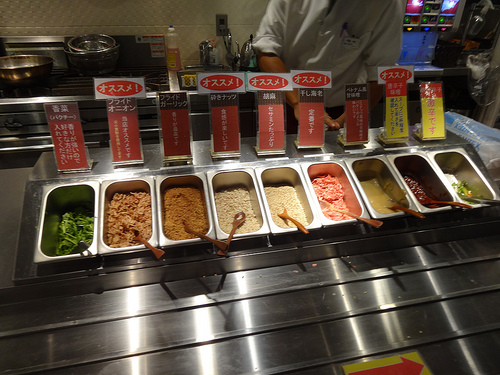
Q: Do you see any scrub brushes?
A: No, there are no scrub brushes.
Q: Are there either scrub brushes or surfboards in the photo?
A: No, there are no scrub brushes or surfboards.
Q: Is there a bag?
A: No, there are no bags.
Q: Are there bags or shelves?
A: No, there are no bags or shelves.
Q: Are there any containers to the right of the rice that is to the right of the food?
A: Yes, there is a container to the right of the rice.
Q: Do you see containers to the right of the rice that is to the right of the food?
A: Yes, there is a container to the right of the rice.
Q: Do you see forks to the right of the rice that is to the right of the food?
A: No, there is a container to the right of the rice.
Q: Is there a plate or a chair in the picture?
A: No, there are no chairs or plates.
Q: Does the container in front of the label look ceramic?
A: No, the container is metallic.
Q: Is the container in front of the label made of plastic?
A: No, the container is made of metal.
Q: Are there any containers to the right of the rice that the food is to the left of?
A: Yes, there is a container to the right of the rice.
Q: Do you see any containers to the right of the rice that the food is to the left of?
A: Yes, there is a container to the right of the rice.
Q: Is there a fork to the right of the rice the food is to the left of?
A: No, there is a container to the right of the rice.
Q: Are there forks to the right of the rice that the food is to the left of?
A: No, there is a container to the right of the rice.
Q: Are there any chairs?
A: No, there are no chairs.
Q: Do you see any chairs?
A: No, there are no chairs.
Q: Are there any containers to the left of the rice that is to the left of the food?
A: Yes, there is a container to the left of the rice.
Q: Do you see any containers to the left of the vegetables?
A: No, the container is to the right of the vegetables.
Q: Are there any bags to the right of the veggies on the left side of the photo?
A: No, there is a container to the right of the vegetables.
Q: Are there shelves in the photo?
A: No, there are no shelves.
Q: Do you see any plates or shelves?
A: No, there are no shelves or plates.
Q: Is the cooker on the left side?
A: Yes, the cooker is on the left of the image.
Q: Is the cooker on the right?
A: No, the cooker is on the left of the image.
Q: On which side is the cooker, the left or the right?
A: The cooker is on the left of the image.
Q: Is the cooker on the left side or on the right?
A: The cooker is on the left of the image.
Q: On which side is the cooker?
A: The cooker is on the left of the image.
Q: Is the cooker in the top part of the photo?
A: Yes, the cooker is in the top of the image.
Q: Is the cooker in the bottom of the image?
A: No, the cooker is in the top of the image.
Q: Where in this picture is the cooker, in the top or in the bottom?
A: The cooker is in the top of the image.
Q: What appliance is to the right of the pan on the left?
A: The appliance is a cooker.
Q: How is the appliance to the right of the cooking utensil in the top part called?
A: The appliance is a cooker.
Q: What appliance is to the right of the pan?
A: The appliance is a cooker.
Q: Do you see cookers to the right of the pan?
A: Yes, there is a cooker to the right of the pan.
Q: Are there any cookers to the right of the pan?
A: Yes, there is a cooker to the right of the pan.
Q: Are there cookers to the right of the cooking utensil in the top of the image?
A: Yes, there is a cooker to the right of the pan.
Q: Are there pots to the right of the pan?
A: No, there is a cooker to the right of the pan.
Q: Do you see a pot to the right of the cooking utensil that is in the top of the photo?
A: No, there is a cooker to the right of the pan.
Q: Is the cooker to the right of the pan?
A: Yes, the cooker is to the right of the pan.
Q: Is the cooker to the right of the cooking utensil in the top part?
A: Yes, the cooker is to the right of the pan.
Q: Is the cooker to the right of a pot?
A: No, the cooker is to the right of the pan.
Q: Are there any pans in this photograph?
A: Yes, there is a pan.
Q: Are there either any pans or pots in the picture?
A: Yes, there is a pan.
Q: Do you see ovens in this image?
A: No, there are no ovens.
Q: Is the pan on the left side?
A: Yes, the pan is on the left of the image.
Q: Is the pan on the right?
A: No, the pan is on the left of the image.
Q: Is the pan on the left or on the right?
A: The pan is on the left of the image.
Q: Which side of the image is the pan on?
A: The pan is on the left of the image.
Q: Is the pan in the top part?
A: Yes, the pan is in the top of the image.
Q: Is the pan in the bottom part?
A: No, the pan is in the top of the image.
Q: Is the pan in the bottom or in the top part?
A: The pan is in the top of the image.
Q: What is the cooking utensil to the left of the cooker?
A: The cooking utensil is a pan.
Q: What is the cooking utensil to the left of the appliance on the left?
A: The cooking utensil is a pan.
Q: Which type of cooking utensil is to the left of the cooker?
A: The cooking utensil is a pan.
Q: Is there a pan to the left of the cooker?
A: Yes, there is a pan to the left of the cooker.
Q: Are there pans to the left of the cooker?
A: Yes, there is a pan to the left of the cooker.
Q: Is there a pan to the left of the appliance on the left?
A: Yes, there is a pan to the left of the cooker.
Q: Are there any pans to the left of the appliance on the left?
A: Yes, there is a pan to the left of the cooker.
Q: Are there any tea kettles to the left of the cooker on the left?
A: No, there is a pan to the left of the cooker.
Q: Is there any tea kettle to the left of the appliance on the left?
A: No, there is a pan to the left of the cooker.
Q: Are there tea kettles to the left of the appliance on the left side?
A: No, there is a pan to the left of the cooker.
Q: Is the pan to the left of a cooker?
A: Yes, the pan is to the left of a cooker.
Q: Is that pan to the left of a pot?
A: No, the pan is to the left of a cooker.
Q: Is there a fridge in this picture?
A: No, there are no refrigerators.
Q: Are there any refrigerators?
A: No, there are no refrigerators.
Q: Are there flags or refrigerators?
A: No, there are no refrigerators or flags.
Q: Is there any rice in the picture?
A: Yes, there is rice.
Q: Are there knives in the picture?
A: No, there are no knives.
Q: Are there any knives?
A: No, there are no knives.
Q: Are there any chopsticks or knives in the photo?
A: No, there are no knives or chopsticks.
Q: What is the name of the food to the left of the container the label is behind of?
A: The food is rice.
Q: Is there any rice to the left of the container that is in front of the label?
A: Yes, there is rice to the left of the container.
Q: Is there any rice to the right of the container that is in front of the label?
A: No, the rice is to the left of the container.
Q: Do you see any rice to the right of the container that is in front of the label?
A: No, the rice is to the left of the container.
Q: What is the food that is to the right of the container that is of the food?
A: The food is rice.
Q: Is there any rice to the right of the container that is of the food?
A: Yes, there is rice to the right of the container.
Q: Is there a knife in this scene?
A: No, there are no knives.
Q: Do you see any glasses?
A: No, there are no glasses.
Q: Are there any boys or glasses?
A: No, there are no glasses or boys.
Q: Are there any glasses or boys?
A: No, there are no glasses or boys.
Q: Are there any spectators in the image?
A: No, there are no spectators.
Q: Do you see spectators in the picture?
A: No, there are no spectators.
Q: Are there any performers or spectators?
A: No, there are no spectators or performers.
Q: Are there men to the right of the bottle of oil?
A: Yes, there is a man to the right of the bottle.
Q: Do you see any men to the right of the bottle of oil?
A: Yes, there is a man to the right of the bottle.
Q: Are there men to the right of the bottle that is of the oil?
A: Yes, there is a man to the right of the bottle.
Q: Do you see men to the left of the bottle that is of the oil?
A: No, the man is to the right of the bottle.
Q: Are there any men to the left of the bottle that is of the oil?
A: No, the man is to the right of the bottle.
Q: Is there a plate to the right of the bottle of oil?
A: No, there is a man to the right of the bottle.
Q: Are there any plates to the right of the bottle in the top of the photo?
A: No, there is a man to the right of the bottle.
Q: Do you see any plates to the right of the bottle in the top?
A: No, there is a man to the right of the bottle.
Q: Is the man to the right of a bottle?
A: Yes, the man is to the right of a bottle.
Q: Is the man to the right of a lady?
A: No, the man is to the right of a bottle.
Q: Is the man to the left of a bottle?
A: No, the man is to the right of a bottle.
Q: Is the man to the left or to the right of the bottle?
A: The man is to the right of the bottle.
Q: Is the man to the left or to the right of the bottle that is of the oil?
A: The man is to the right of the bottle.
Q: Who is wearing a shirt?
A: The man is wearing a shirt.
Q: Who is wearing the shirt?
A: The man is wearing a shirt.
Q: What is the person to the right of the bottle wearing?
A: The man is wearing a shirt.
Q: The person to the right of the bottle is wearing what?
A: The man is wearing a shirt.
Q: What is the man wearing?
A: The man is wearing a shirt.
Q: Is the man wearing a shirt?
A: Yes, the man is wearing a shirt.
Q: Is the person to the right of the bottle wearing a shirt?
A: Yes, the man is wearing a shirt.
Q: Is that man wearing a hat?
A: No, the man is wearing a shirt.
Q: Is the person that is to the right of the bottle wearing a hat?
A: No, the man is wearing a shirt.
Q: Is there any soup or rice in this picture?
A: Yes, there is rice.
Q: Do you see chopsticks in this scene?
A: No, there are no chopsticks.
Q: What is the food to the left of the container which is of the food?
A: The food is rice.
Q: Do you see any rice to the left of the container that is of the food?
A: Yes, there is rice to the left of the container.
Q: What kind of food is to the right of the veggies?
A: The food is rice.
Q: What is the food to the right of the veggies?
A: The food is rice.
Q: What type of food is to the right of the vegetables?
A: The food is rice.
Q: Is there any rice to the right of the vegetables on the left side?
A: Yes, there is rice to the right of the vegetables.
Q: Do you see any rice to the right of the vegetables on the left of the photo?
A: Yes, there is rice to the right of the vegetables.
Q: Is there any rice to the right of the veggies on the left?
A: Yes, there is rice to the right of the vegetables.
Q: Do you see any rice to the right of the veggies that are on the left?
A: Yes, there is rice to the right of the vegetables.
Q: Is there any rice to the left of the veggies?
A: No, the rice is to the right of the veggies.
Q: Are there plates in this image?
A: No, there are no plates.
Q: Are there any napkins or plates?
A: No, there are no plates or napkins.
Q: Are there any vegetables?
A: Yes, there are vegetables.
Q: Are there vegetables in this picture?
A: Yes, there are vegetables.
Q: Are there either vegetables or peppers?
A: Yes, there are vegetables.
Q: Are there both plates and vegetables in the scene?
A: No, there are vegetables but no plates.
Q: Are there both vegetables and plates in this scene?
A: No, there are vegetables but no plates.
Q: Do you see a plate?
A: No, there are no plates.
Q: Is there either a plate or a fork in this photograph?
A: No, there are no plates or forks.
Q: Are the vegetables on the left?
A: Yes, the vegetables are on the left of the image.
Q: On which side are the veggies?
A: The veggies are on the left of the image.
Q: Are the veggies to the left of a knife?
A: No, the veggies are to the left of a container.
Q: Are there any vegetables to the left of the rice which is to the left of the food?
A: Yes, there are vegetables to the left of the rice.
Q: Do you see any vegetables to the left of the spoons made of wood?
A: Yes, there are vegetables to the left of the spoons.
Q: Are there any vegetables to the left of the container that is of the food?
A: Yes, there are vegetables to the left of the container.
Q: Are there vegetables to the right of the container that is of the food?
A: No, the vegetables are to the left of the container.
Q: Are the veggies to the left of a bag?
A: No, the veggies are to the left of a container.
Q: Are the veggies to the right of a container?
A: No, the veggies are to the left of a container.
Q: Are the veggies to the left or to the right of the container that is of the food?
A: The veggies are to the left of the container.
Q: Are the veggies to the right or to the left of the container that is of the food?
A: The veggies are to the left of the container.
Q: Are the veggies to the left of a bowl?
A: No, the veggies are to the left of a container.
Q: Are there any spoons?
A: Yes, there is a spoon.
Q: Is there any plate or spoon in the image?
A: Yes, there is a spoon.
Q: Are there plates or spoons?
A: Yes, there is a spoon.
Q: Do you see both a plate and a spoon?
A: No, there is a spoon but no plates.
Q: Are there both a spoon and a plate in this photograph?
A: No, there is a spoon but no plates.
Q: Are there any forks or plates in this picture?
A: No, there are no plates or forks.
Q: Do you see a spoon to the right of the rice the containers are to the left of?
A: Yes, there are spoons to the right of the rice.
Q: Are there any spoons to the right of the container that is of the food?
A: Yes, there are spoons to the right of the container.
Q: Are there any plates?
A: No, there are no plates.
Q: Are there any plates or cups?
A: No, there are no plates or cups.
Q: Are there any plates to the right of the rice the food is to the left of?
A: No, there is a container to the right of the rice.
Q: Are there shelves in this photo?
A: No, there are no shelves.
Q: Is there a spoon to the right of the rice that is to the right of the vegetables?
A: Yes, there are spoons to the right of the rice.